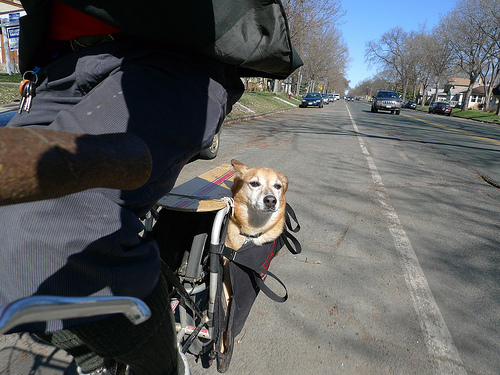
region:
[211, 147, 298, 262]
dog with a street in the background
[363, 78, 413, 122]
late model suv driving on street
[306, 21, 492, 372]
road dividing line in white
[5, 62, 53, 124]
set of house and car keys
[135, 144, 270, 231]
wooden skateboard with red stripe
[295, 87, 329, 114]
car with trees in the background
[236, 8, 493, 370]
ordinary street in the daytime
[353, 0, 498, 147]
row of trees in a neighborhood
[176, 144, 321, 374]
bike rack modified to be a dog carrier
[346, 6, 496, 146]
row of houses along a street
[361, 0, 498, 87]
a bunch of brown trees.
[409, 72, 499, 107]
a row of houses.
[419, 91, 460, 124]
a burgundy car is parked in front of the house.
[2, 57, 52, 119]
a man is wearing keys on his belt.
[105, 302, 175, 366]
a man is wearing a pair of green socks.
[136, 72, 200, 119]
a man is wearing grey pants.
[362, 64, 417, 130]
a blue van is driving down the street.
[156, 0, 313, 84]
a man is carrying a black back pack.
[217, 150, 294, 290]
a brown and beige dog.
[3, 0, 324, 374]
a man is riding a bike down the street.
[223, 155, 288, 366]
Dog tied on a bicycle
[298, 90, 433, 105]
Vehicles on the road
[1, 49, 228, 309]
Man wearing dark blue pants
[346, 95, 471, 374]
White line dividing the oad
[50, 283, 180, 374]
Pair of green socks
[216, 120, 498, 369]
Rough grey tarmacked road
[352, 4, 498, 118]
Bare trees along the road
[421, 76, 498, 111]
Buildings beside the road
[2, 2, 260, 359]
Man riding a bicycle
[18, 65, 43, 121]
Keys hanging from the belt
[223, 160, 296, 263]
dog in a carrying bag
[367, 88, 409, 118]
car on the street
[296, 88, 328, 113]
car parked on the street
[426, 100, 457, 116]
car parked on the street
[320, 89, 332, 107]
car parked on the street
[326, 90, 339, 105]
car parked on the street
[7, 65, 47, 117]
group of keys with black heads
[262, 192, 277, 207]
black nose of a dog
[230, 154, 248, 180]
ear of a dog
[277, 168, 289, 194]
ear of a dog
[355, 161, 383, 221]
white line on street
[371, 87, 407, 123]
dark jeep on street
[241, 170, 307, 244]
dog riding in carrier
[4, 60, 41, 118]
set of keys hanging from bag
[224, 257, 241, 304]
dog carrier is black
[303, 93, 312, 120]
dark car parked on street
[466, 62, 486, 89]
bare tree in distance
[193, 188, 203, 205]
tan board with red stripe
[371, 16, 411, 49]
sky is a faded blue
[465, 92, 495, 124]
tan house off street